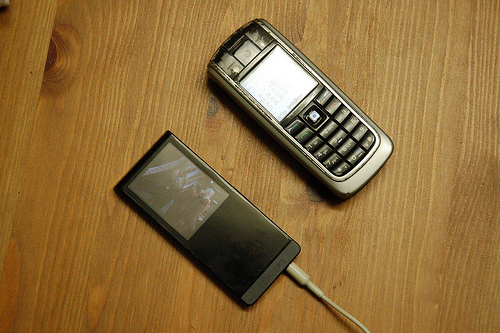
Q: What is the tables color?
A: Brown.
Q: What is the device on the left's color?
A: Black.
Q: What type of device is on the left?
A: Ipod Mini.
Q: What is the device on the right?
A: Cell Phone.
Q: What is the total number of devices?
A: 2.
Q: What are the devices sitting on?
A: Table.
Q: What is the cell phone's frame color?
A: Gray.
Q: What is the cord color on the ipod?
A: Gray.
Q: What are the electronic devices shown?
A: Cell phone.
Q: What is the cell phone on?
A: Wooden table.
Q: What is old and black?
A: The video player.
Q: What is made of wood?
A: The table top.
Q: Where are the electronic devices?
A: On a table.